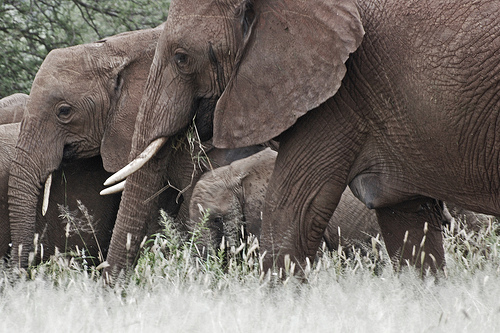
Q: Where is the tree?
A: To the left.